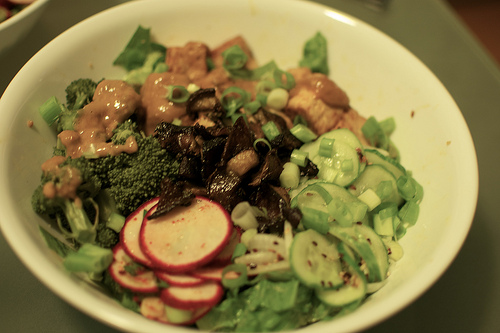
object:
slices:
[110, 198, 244, 325]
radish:
[138, 194, 234, 275]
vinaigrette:
[33, 70, 198, 202]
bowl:
[0, 0, 52, 46]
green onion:
[221, 44, 249, 71]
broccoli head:
[88, 132, 180, 214]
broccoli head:
[64, 77, 98, 112]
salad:
[31, 23, 425, 329]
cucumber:
[289, 229, 346, 292]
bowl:
[0, 0, 481, 332]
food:
[30, 25, 424, 331]